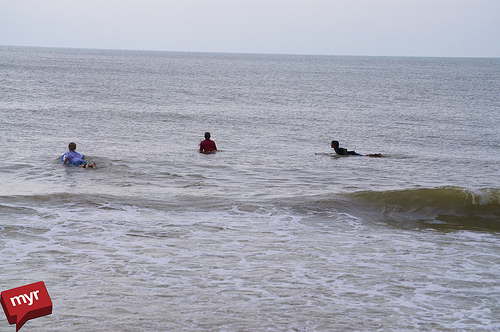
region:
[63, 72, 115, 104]
the water is calm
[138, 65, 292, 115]
the water is calm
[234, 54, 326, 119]
the water is calm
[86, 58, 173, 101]
the water is calm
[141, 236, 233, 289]
the water is calm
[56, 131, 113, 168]
a boy on the water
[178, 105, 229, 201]
a boy on the water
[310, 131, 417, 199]
a boy on the water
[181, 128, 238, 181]
a boy on the water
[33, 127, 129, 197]
a boy on the water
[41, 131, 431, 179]
three swimmers in water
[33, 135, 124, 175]
boy swimming in water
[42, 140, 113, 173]
swimmer in blue clothes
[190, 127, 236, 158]
swimmer in water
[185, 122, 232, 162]
swimmer in red clothing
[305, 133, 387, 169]
swimmer facing left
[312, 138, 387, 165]
swimming in dark clothing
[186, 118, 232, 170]
swimmer sitting up in water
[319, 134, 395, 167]
boy swimming to the left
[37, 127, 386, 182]
three kids swimming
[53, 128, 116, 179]
boy on surfboard in water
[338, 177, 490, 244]
wave in the ocean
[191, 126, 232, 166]
boy sitting in the ocean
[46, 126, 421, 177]
three boys in the ocean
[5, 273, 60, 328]
company design in corner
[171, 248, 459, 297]
water of an ocean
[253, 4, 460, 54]
blue sky in the distance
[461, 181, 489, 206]
crest of a wave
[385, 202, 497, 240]
shadow from a wave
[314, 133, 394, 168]
boy lying on a surfboard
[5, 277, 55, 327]
Photo owner identification label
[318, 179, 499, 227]
Ocean wave beginning to break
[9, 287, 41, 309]
Letters myr on red label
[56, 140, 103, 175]
Surfer paddling out to waves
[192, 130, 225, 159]
Surfer paddling out to waves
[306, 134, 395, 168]
Man laying on surfboard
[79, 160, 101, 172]
Bare feet of man on surfboard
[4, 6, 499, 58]
cloudy sky in background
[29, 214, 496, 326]
White foam on water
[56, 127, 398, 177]
Three surfers paddling to catch waves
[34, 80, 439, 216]
swimmers in the water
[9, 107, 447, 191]
three swimmers in the water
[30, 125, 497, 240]
waves in the water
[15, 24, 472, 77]
the skyline and the water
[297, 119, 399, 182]
this person is extended in the water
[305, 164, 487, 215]
a large wave on top of the water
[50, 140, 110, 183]
this person is wearing a blue shirt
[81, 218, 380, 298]
the water is gray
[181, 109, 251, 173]
this person has on a red shirt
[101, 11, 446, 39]
the sky is cloudy